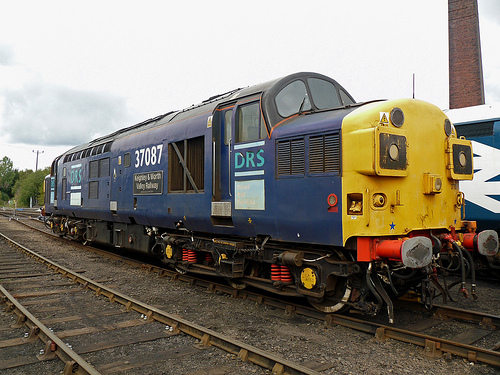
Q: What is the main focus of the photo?
A: A train.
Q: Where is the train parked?
A: On the tracks.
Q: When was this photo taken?
A: Daytime.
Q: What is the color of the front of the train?
A: Yellow.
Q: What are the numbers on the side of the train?
A: 37087.